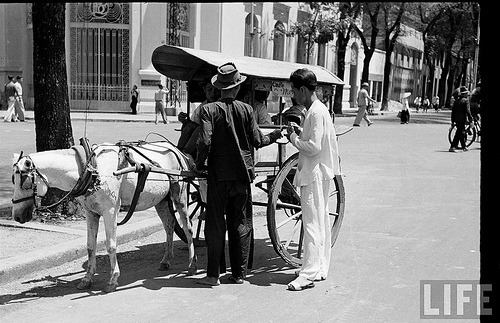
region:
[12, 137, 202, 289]
a white horse pulling a buggy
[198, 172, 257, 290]
black pants on a man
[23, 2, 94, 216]
a tree trunk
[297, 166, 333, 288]
white pants on a man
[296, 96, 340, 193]
a white shirt on a man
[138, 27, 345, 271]
a wagon connected to a horse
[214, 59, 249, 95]
a hat on a man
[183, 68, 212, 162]
a man sitting in a wagon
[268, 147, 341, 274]
a wagon wheel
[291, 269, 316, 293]
white shoes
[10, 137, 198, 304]
a white horse pulling a carriage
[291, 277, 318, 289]
a white shoe on a man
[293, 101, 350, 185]
a white shirt on a man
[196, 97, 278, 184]
a black shirt on a man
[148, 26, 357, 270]
a carriage connected to a horse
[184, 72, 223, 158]
a man riding in a carriage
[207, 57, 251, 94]
hat on man's head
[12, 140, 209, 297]
white horse in street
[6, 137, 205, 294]
white horse pulling stagecoach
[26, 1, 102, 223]
brown tree trunk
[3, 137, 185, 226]
harnass on white horse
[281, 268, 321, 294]
white sandals on man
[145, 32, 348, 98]
roof on carriage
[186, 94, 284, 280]
black suit on man with hat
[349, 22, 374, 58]
tree branches attached to tree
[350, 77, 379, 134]
man crossing the street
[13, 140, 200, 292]
a white horse pulling a cart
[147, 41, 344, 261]
the two-wheeled cart behind the horse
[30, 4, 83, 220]
tree trunk next to horse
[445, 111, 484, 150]
rear wheel of bicycle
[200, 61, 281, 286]
man in suit with a hat by cart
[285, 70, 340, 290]
man in white outfit by cart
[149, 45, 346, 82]
the roof on the cart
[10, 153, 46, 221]
the horse's head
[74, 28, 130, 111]
large doors to building across the street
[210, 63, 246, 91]
hat on man with dark suit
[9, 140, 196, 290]
a white horse on a road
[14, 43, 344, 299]
a white horse pulling a wagon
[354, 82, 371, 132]
a man crossing a street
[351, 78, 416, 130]
a man with a dog crossing a street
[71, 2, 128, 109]
a large window on a building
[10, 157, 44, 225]
a harness on a horse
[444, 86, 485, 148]
a person on a bike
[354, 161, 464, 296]
a concrete steet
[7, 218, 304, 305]
a shadow on the street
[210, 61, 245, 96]
a hat on a mans head